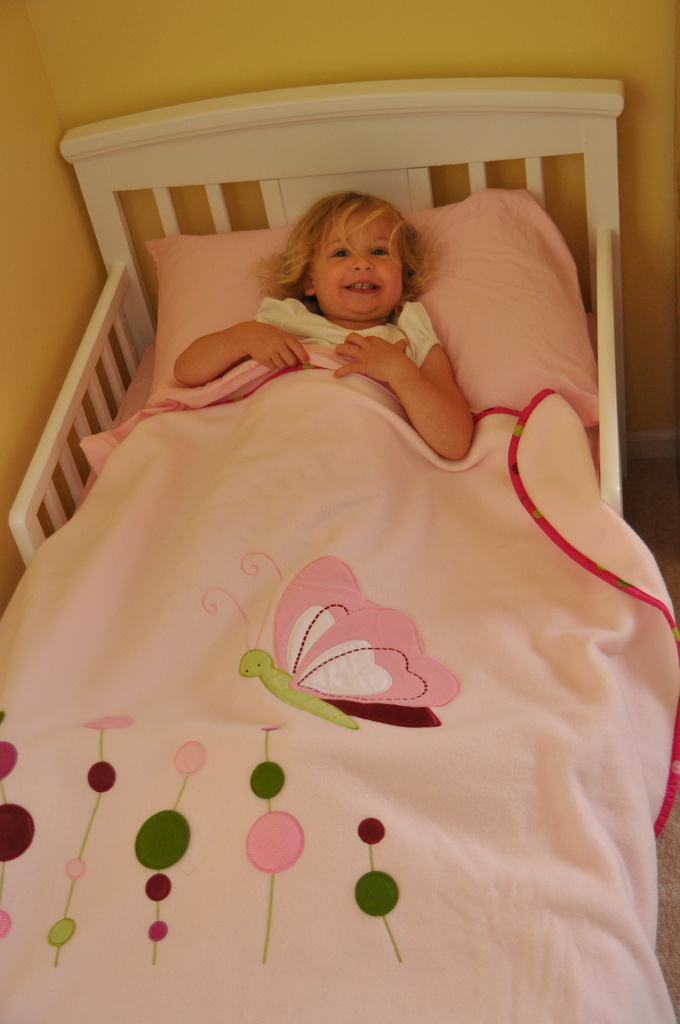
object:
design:
[354, 870, 400, 916]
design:
[246, 810, 306, 875]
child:
[171, 189, 474, 465]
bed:
[7, 77, 629, 578]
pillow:
[144, 187, 597, 430]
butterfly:
[201, 551, 460, 732]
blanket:
[0, 364, 680, 1024]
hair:
[245, 187, 451, 316]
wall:
[0, 0, 680, 440]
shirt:
[255, 296, 442, 372]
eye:
[330, 249, 351, 258]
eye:
[371, 246, 390, 257]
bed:
[0, 184, 680, 1024]